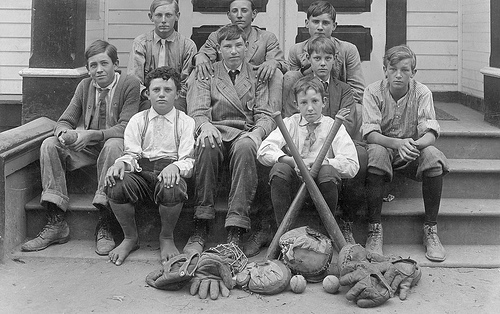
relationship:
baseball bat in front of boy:
[266, 112, 344, 262] [254, 76, 360, 244]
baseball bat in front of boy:
[266, 112, 344, 262] [185, 32, 283, 256]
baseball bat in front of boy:
[266, 112, 344, 262] [104, 65, 196, 266]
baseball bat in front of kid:
[266, 112, 344, 262] [17, 37, 144, 256]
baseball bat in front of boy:
[271, 109, 350, 244] [254, 76, 360, 244]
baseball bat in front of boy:
[271, 109, 350, 244] [185, 32, 283, 256]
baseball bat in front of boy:
[271, 109, 350, 244] [104, 65, 196, 266]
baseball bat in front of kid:
[271, 109, 350, 244] [17, 37, 144, 256]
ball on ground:
[290, 274, 306, 293] [9, 244, 493, 311]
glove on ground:
[338, 259, 404, 306] [4, 257, 497, 312]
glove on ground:
[378, 257, 416, 299] [4, 257, 497, 312]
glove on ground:
[189, 253, 234, 300] [4, 257, 497, 312]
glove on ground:
[144, 251, 199, 289] [4, 257, 497, 312]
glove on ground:
[237, 257, 294, 294] [4, 257, 497, 312]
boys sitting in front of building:
[18, 0, 454, 269] [0, 2, 493, 261]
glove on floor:
[380, 255, 419, 300] [2, 260, 497, 312]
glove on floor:
[338, 254, 422, 307] [2, 260, 497, 312]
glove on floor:
[235, 259, 291, 295] [2, 260, 497, 312]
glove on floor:
[144, 251, 199, 289] [2, 260, 497, 312]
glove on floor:
[189, 253, 234, 300] [2, 260, 497, 312]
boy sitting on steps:
[358, 43, 451, 262] [39, 88, 497, 253]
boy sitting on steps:
[254, 76, 360, 244] [39, 88, 497, 253]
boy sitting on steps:
[199, 31, 275, 246] [39, 88, 497, 253]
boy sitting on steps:
[115, 76, 191, 260] [39, 88, 497, 253]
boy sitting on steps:
[39, 38, 126, 254] [39, 88, 497, 253]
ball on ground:
[321, 275, 341, 293] [5, 233, 496, 311]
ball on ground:
[290, 274, 306, 293] [5, 233, 496, 311]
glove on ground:
[334, 252, 384, 299] [5, 233, 496, 311]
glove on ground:
[189, 253, 234, 300] [5, 233, 496, 311]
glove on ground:
[142, 248, 200, 288] [5, 233, 496, 311]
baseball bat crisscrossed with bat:
[269, 110, 348, 252] [261, 104, 343, 258]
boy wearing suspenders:
[104, 65, 196, 266] [137, 104, 181, 159]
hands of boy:
[195, 52, 277, 84] [191, 0, 268, 67]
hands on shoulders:
[195, 52, 277, 84] [188, 60, 282, 98]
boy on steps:
[358, 43, 451, 262] [22, 98, 499, 268]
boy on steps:
[254, 77, 361, 234] [22, 98, 499, 268]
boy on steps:
[185, 32, 283, 256] [22, 98, 499, 268]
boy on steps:
[104, 65, 196, 266] [22, 98, 499, 268]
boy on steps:
[20, 39, 143, 256] [22, 98, 499, 268]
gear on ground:
[152, 220, 429, 311] [9, 244, 493, 311]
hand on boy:
[253, 59, 280, 84] [358, 43, 451, 262]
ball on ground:
[290, 274, 306, 293] [27, 215, 497, 312]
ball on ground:
[321, 275, 341, 293] [9, 244, 493, 311]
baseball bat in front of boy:
[269, 110, 348, 252] [257, 83, 359, 230]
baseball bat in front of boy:
[263, 114, 346, 260] [257, 83, 359, 230]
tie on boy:
[92, 86, 111, 128] [20, 39, 143, 256]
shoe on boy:
[422, 223, 448, 267] [362, 37, 448, 258]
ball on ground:
[317, 274, 343, 293] [4, 257, 497, 312]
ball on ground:
[290, 274, 310, 296] [4, 257, 497, 312]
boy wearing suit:
[185, 32, 283, 256] [188, 58, 279, 229]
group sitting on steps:
[17, 0, 449, 269] [24, 117, 496, 267]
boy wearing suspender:
[104, 65, 196, 266] [173, 106, 180, 151]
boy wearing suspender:
[104, 65, 196, 266] [139, 108, 146, 148]